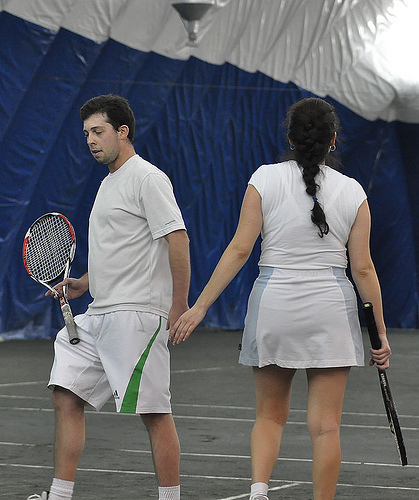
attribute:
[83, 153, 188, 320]
shirt — white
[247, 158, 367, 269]
shirt — white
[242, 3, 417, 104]
canopy — white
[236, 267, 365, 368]
skirt — white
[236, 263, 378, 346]
skirt — grey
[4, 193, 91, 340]
racket — tennis 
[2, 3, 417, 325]
canopy — blue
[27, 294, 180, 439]
shorts — green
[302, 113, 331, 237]
hair — braided